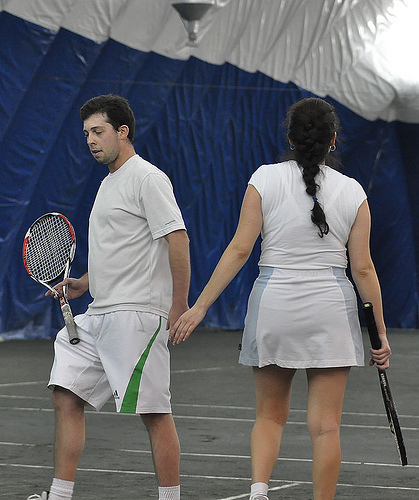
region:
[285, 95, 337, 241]
loosely braided long dark hair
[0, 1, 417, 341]
blue and white fabric tent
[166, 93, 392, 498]
woman wearing a short tennis skirt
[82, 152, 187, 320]
white t-shirt bearing brand name on sleeve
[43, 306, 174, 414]
white shorts with green side stripe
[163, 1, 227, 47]
hanging electrical fixture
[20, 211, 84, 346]
hand holding a tennis racket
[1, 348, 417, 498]
lines on playing surface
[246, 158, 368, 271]
bra visible through light weight t-shirt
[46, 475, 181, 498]
two crew sock cuffs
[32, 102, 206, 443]
a man playing tennis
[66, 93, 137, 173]
the head of a man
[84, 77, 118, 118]
the hair of a man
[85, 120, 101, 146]
the eyes of a man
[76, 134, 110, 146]
the nose of a man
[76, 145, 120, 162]
the mouth of a man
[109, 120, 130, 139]
the ear of a man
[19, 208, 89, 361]
a black and white tennis racket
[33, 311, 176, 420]
the shorts of a man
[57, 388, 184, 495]
the legs of a man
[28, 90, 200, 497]
a man holding a tennis racket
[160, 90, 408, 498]
a woman holding a tennis racket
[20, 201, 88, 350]
a red and white tennis racket in a man's hand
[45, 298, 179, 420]
green and white tennis shorts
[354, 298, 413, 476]
a black tennis racket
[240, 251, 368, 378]
a grey and white tennis skirt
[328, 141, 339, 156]
a silver ear ring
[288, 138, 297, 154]
a silver ear ring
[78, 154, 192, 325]
a white tennis shirt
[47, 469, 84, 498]
a white sock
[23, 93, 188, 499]
Man standing on the tennis court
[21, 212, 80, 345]
Racket in the man's hand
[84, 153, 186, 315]
Shirt on the man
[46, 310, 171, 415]
Shorts on the man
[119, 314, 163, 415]
Green stripe on the man's shorts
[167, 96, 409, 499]
Woman in the tennis court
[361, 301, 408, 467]
Racket in the woman's hand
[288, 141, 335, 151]
Earrings on the woman's ears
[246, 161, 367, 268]
Shirt on the woman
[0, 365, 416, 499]
White lines on the tennis court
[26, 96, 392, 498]
The couple is playing tennis.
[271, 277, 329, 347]
The skirt is white.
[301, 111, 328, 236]
The woman's hair is braided.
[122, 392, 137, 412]
The shorts have a green graphic.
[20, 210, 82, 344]
The man holds a tennis racquet.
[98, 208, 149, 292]
The shirt is white.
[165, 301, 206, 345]
The couple's hands are touching.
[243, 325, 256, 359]
The skirt is grey.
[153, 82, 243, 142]
The canopy is blue.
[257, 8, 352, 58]
The canopy is white.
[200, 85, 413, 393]
woman holding a tennis racket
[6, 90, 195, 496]
man holding a tennis racket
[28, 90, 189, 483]
man wearing white shirt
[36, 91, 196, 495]
man wearing white shorts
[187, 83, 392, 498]
woman wearing white shirt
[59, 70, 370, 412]
the people are standing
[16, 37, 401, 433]
the people are playing tennis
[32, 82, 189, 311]
the man is playing tennis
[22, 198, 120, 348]
the tennis racket is red and black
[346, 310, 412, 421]
this tennis racket is black